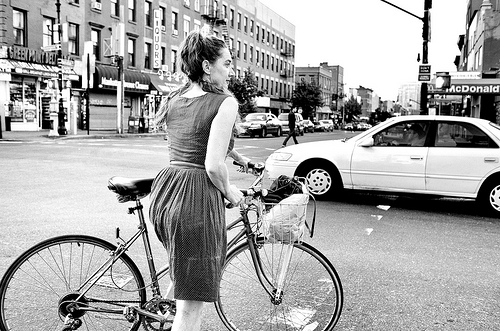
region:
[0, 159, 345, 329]
a woman's bicycle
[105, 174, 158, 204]
a black bicycle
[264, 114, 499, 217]
a white car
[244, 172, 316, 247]
a metal basket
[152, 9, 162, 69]
A white sign that says liquors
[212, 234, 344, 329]
a bicycle wheel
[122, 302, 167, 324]
a bicycle pedal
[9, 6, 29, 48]
a window in a building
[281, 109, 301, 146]
man in the middle of the street.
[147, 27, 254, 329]
a woman in a dress.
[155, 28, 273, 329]
A woman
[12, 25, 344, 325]
A woman with a bicycle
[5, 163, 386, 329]
A bicycle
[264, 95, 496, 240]
A white car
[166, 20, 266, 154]
A woman with long hair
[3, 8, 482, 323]
A black and white picture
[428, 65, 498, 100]
A McDonalds sign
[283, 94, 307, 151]
A person walking across the street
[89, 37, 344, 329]
A woman with a bike with a basket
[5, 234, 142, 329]
A rear bike wheel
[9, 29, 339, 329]
woman walking a bicycle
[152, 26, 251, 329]
woman in a sleeveless dress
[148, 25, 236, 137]
woman with a long ponytail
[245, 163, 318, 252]
wire basket on bicycle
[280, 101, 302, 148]
person crossing the street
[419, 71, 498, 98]
mcdonald's restaurant awning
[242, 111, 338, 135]
cars parallel parked along curb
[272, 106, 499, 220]
passenger car crossing intersection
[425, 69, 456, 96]
pedestrian stoplight with don't cross signal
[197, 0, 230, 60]
fire escape on side of building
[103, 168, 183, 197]
Seat on a bike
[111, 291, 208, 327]
Pedal on a bike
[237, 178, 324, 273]
Basket on a bike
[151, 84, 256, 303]
Dress on a woman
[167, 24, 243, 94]
Dark hair on a woman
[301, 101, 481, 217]
White car on a street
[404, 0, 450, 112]
Light pole by a road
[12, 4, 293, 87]
Windows on a building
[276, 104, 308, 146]
Man walking on a road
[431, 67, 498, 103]
Mcdonalds sign on a building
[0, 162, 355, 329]
bicycle with basket above front wheel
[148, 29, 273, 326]
girl wearing a dress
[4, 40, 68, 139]
deli across the street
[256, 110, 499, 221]
four door car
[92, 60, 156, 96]
awning over a storefront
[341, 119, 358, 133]
car with headlights on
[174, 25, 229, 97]
medium length ponytail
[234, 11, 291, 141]
four story building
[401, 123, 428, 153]
man driving a car